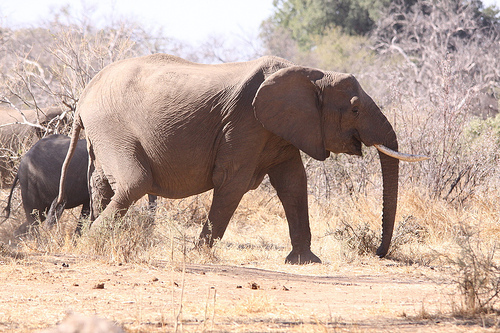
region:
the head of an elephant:
[286, 58, 391, 163]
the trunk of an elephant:
[372, 151, 397, 261]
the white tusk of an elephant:
[375, 138, 435, 164]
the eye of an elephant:
[347, 100, 363, 118]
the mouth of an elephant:
[352, 135, 372, 160]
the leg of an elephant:
[262, 156, 317, 246]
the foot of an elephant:
[282, 241, 324, 266]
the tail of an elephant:
[38, 105, 84, 226]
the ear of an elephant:
[243, 56, 339, 166]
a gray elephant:
[41, 52, 418, 267]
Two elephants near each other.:
[0, 41, 445, 266]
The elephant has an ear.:
[245, 60, 330, 160]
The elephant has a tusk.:
[365, 125, 440, 165]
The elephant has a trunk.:
[355, 96, 410, 266]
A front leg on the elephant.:
[245, 145, 331, 275]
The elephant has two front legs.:
[175, 125, 345, 280]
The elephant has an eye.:
[347, 97, 359, 118]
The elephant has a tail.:
[36, 101, 92, 246]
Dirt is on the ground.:
[140, 270, 395, 310]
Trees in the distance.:
[265, 0, 499, 55]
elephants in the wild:
[15, 22, 496, 267]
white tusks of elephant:
[366, 136, 441, 173]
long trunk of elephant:
[353, 122, 420, 281]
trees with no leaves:
[422, 36, 476, 201]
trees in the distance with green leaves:
[276, 5, 377, 37]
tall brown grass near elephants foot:
[34, 216, 187, 278]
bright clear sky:
[184, 11, 236, 36]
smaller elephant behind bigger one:
[18, 124, 111, 234]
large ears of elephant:
[265, 54, 336, 166]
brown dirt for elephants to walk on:
[107, 244, 394, 314]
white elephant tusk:
[371, 140, 434, 167]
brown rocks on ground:
[221, 279, 296, 294]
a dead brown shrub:
[438, 231, 499, 327]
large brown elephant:
[68, 59, 423, 266]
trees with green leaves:
[293, 0, 380, 65]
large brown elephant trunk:
[374, 160, 404, 258]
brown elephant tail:
[53, 117, 84, 209]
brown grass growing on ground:
[401, 205, 452, 262]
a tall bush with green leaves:
[459, 120, 499, 175]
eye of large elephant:
[346, 95, 371, 117]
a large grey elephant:
[51, 48, 456, 281]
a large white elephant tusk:
[352, 136, 444, 169]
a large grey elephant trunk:
[360, 113, 424, 268]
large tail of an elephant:
[36, 98, 98, 233]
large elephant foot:
[270, 246, 335, 272]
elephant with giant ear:
[44, 41, 423, 285]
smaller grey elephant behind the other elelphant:
[6, 116, 133, 253]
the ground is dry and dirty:
[0, 188, 475, 331]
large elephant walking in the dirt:
[37, 44, 443, 282]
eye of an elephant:
[345, 98, 372, 120]